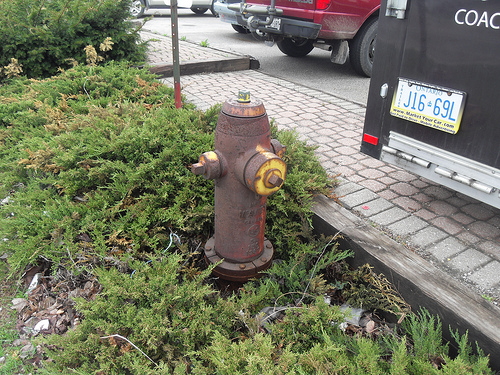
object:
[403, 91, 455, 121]
letters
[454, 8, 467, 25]
frame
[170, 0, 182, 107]
post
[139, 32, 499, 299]
brick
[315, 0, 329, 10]
tail light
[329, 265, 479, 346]
log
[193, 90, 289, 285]
hydrant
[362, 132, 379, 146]
brake light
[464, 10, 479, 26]
letter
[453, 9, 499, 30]
letters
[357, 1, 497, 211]
car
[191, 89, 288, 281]
fruit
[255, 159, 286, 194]
yellow paint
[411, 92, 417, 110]
letter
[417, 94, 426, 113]
letter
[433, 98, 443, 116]
letter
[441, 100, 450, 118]
letter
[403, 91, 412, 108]
letter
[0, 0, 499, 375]
bushes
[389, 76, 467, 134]
license plate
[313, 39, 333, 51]
exhaust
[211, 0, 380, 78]
truck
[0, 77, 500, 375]
ground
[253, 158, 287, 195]
cap